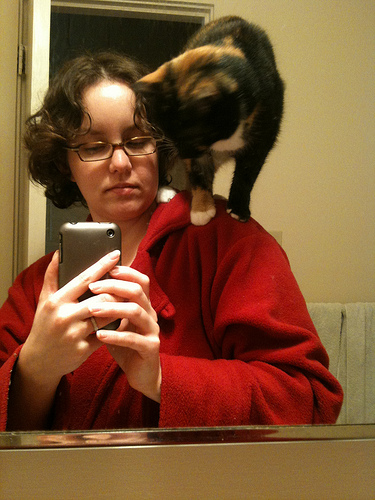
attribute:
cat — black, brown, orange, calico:
[137, 14, 285, 227]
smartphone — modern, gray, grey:
[57, 220, 123, 336]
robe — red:
[2, 188, 347, 428]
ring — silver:
[88, 312, 99, 334]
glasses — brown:
[55, 133, 165, 166]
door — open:
[16, 0, 46, 280]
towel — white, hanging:
[302, 302, 375, 427]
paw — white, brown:
[188, 191, 215, 227]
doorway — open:
[47, 0, 204, 256]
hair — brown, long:
[23, 50, 179, 208]